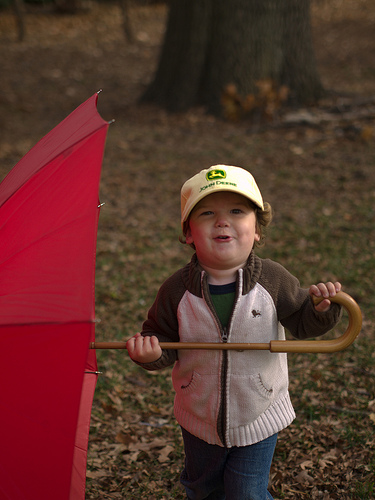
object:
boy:
[128, 164, 345, 498]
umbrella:
[1, 90, 365, 500]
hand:
[126, 330, 163, 365]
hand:
[307, 281, 341, 313]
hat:
[179, 162, 264, 235]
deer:
[205, 169, 226, 180]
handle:
[94, 291, 363, 353]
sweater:
[132, 247, 344, 450]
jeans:
[183, 417, 279, 497]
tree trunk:
[136, 2, 350, 127]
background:
[3, 2, 374, 161]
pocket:
[236, 375, 274, 428]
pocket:
[178, 370, 218, 422]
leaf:
[135, 436, 167, 450]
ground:
[2, 30, 374, 496]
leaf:
[291, 456, 317, 474]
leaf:
[155, 443, 174, 465]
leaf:
[105, 390, 125, 415]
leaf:
[315, 451, 338, 470]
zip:
[197, 266, 246, 451]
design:
[251, 309, 261, 319]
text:
[199, 180, 237, 194]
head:
[184, 165, 261, 271]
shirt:
[208, 279, 240, 333]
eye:
[230, 207, 244, 215]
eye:
[200, 210, 215, 216]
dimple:
[240, 228, 251, 241]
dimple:
[194, 234, 204, 245]